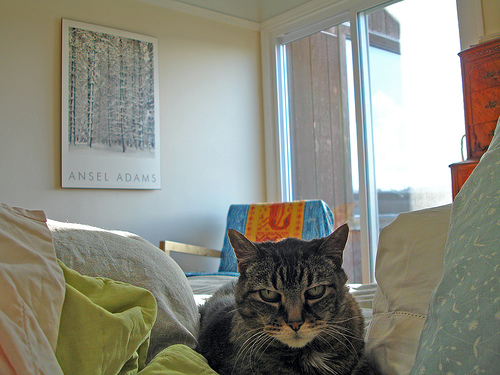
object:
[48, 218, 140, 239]
sunlight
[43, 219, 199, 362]
blanket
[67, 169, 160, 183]
print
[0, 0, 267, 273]
wall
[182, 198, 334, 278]
fabric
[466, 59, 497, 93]
hutch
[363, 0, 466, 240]
window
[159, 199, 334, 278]
chair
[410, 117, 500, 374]
blanket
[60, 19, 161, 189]
poster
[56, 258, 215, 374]
blanket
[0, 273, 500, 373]
bed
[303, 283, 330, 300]
eyes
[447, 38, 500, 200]
chest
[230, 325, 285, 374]
whiskers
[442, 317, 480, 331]
pattern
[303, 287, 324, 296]
pupils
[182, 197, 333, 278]
covering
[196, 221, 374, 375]
cat